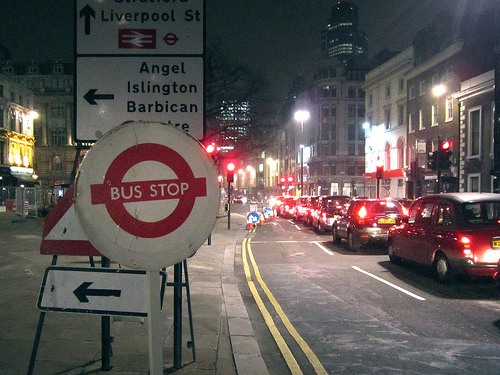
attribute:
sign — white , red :
[76, 118, 227, 276]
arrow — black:
[65, 279, 143, 306]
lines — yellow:
[234, 237, 324, 367]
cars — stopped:
[275, 150, 498, 295]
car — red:
[387, 186, 497, 286]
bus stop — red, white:
[75, 120, 224, 272]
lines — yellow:
[238, 231, 320, 371]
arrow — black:
[72, 282, 126, 300]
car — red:
[384, 192, 476, 280]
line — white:
[351, 261, 430, 303]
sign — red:
[92, 147, 213, 237]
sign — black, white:
[35, 268, 167, 315]